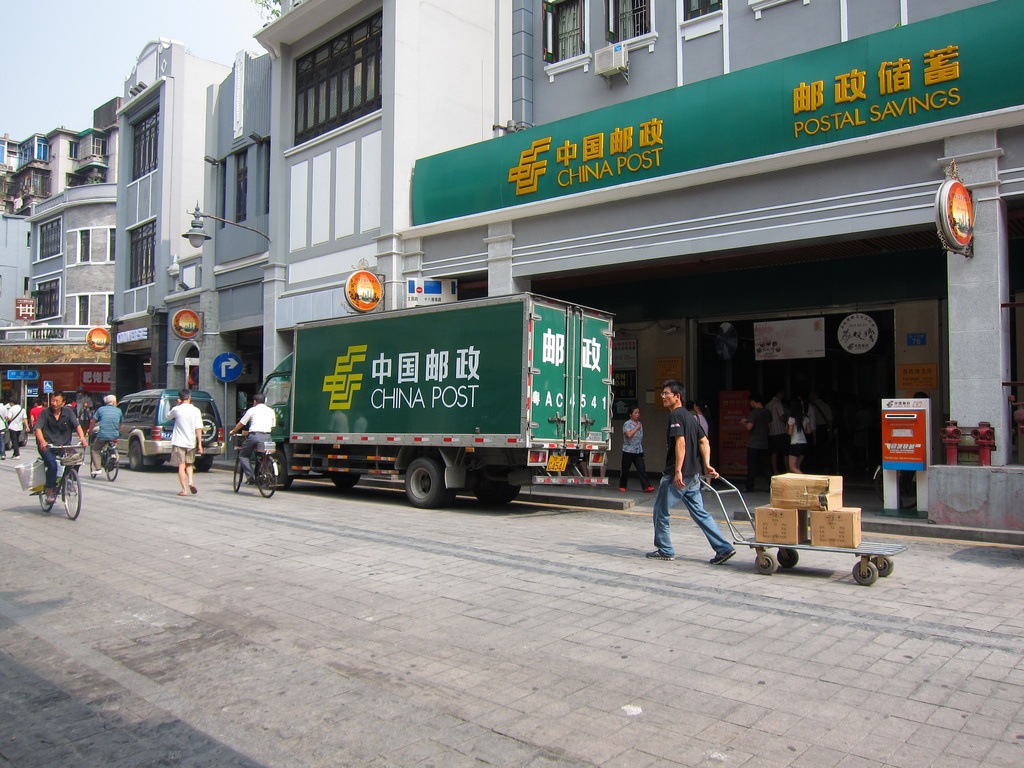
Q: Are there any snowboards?
A: No, there are no snowboards.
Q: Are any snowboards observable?
A: No, there are no snowboards.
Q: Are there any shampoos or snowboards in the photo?
A: No, there are no snowboards or shampoos.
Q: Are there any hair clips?
A: No, there are no hair clips.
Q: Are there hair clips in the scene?
A: No, there are no hair clips.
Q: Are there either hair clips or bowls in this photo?
A: No, there are no hair clips or bowls.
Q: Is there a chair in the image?
A: No, there are no chairs.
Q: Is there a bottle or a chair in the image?
A: No, there are no chairs or bottles.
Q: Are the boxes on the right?
A: Yes, the boxes are on the right of the image.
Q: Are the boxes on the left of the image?
A: No, the boxes are on the right of the image.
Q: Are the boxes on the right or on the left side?
A: The boxes are on the right of the image.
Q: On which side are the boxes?
A: The boxes are on the right of the image.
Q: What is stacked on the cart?
A: The boxes are stacked on the cart.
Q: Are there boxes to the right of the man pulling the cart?
A: Yes, there are boxes to the right of the man.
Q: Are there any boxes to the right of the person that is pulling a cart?
A: Yes, there are boxes to the right of the man.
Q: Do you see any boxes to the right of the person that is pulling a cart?
A: Yes, there are boxes to the right of the man.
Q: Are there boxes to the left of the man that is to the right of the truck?
A: No, the boxes are to the right of the man.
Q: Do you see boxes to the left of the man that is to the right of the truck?
A: No, the boxes are to the right of the man.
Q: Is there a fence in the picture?
A: No, there are no fences.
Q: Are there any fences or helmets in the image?
A: No, there are no fences or helmets.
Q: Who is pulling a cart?
A: The man is pulling a cart.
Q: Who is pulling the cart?
A: The man is pulling a cart.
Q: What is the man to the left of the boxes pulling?
A: The man is pulling a cart.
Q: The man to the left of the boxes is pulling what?
A: The man is pulling a cart.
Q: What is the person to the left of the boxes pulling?
A: The man is pulling a cart.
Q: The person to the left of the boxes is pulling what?
A: The man is pulling a cart.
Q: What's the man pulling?
A: The man is pulling a cart.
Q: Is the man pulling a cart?
A: Yes, the man is pulling a cart.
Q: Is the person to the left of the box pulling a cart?
A: Yes, the man is pulling a cart.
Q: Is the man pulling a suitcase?
A: No, the man is pulling a cart.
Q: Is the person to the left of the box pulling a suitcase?
A: No, the man is pulling a cart.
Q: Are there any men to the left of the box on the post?
A: Yes, there is a man to the left of the box.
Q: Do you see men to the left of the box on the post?
A: Yes, there is a man to the left of the box.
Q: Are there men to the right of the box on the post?
A: No, the man is to the left of the box.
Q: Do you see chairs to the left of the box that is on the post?
A: No, there is a man to the left of the box.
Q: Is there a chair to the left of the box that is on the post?
A: No, there is a man to the left of the box.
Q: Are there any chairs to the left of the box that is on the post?
A: No, there is a man to the left of the box.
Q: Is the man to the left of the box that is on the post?
A: Yes, the man is to the left of the box.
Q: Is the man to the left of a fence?
A: No, the man is to the left of the box.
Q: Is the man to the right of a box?
A: No, the man is to the left of a box.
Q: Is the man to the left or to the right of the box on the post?
A: The man is to the left of the box.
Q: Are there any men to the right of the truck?
A: Yes, there is a man to the right of the truck.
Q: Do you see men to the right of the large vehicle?
A: Yes, there is a man to the right of the truck.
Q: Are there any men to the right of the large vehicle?
A: Yes, there is a man to the right of the truck.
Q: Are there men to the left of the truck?
A: No, the man is to the right of the truck.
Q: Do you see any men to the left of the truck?
A: No, the man is to the right of the truck.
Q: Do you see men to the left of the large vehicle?
A: No, the man is to the right of the truck.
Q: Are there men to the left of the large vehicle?
A: No, the man is to the right of the truck.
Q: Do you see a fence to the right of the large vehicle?
A: No, there is a man to the right of the truck.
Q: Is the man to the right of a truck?
A: Yes, the man is to the right of a truck.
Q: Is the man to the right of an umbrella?
A: No, the man is to the right of a truck.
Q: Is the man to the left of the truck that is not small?
A: No, the man is to the right of the truck.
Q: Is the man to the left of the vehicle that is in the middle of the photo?
A: No, the man is to the right of the truck.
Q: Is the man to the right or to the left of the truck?
A: The man is to the right of the truck.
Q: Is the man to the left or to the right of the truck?
A: The man is to the right of the truck.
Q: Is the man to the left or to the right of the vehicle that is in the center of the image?
A: The man is to the right of the truck.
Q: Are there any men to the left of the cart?
A: Yes, there is a man to the left of the cart.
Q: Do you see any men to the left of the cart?
A: Yes, there is a man to the left of the cart.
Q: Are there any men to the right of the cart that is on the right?
A: No, the man is to the left of the cart.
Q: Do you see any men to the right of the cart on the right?
A: No, the man is to the left of the cart.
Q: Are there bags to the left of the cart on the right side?
A: No, there is a man to the left of the cart.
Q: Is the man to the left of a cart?
A: Yes, the man is to the left of a cart.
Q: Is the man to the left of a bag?
A: No, the man is to the left of a cart.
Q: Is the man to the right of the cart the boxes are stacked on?
A: No, the man is to the left of the cart.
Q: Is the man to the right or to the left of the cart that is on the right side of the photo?
A: The man is to the left of the cart.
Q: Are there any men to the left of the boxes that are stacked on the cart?
A: Yes, there is a man to the left of the boxes.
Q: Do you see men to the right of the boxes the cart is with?
A: No, the man is to the left of the boxes.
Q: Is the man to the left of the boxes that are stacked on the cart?
A: Yes, the man is to the left of the boxes.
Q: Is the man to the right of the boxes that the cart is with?
A: No, the man is to the left of the boxes.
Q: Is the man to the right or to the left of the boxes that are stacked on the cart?
A: The man is to the left of the boxes.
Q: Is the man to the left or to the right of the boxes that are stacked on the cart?
A: The man is to the left of the boxes.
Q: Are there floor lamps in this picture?
A: No, there are no floor lamps.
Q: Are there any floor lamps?
A: No, there are no floor lamps.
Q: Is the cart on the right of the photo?
A: Yes, the cart is on the right of the image.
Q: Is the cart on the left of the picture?
A: No, the cart is on the right of the image.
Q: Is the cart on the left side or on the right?
A: The cart is on the right of the image.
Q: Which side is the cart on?
A: The cart is on the right of the image.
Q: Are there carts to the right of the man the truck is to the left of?
A: Yes, there is a cart to the right of the man.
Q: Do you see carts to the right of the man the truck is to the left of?
A: Yes, there is a cart to the right of the man.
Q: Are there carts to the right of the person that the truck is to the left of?
A: Yes, there is a cart to the right of the man.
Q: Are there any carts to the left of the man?
A: No, the cart is to the right of the man.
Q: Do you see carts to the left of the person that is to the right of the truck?
A: No, the cart is to the right of the man.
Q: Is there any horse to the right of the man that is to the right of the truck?
A: No, there is a cart to the right of the man.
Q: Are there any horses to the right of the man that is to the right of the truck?
A: No, there is a cart to the right of the man.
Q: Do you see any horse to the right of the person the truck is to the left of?
A: No, there is a cart to the right of the man.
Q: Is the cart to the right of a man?
A: Yes, the cart is to the right of a man.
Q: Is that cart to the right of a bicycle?
A: No, the cart is to the right of a man.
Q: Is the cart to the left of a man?
A: No, the cart is to the right of a man.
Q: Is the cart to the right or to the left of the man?
A: The cart is to the right of the man.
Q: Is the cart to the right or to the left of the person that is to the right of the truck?
A: The cart is to the right of the man.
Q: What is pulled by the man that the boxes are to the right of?
A: The cart is pulled by the man.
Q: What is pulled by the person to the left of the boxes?
A: The cart is pulled by the man.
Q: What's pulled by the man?
A: The cart is pulled by the man.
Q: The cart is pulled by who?
A: The cart is pulled by the man.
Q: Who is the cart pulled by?
A: The cart is pulled by the man.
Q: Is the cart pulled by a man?
A: Yes, the cart is pulled by a man.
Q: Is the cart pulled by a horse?
A: No, the cart is pulled by a man.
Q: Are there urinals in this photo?
A: No, there are no urinals.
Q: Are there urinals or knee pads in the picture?
A: No, there are no urinals or knee pads.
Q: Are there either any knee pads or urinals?
A: No, there are no urinals or knee pads.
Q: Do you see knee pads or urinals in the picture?
A: No, there are no urinals or knee pads.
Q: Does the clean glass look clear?
A: Yes, the glass is clear.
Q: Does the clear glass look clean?
A: Yes, the glass is clean.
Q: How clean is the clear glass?
A: The glass is clean.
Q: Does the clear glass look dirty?
A: No, the glass is clean.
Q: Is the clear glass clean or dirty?
A: The glass is clean.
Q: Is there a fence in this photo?
A: No, there are no fences.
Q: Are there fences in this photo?
A: No, there are no fences.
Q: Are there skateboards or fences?
A: No, there are no fences or skateboards.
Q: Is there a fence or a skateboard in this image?
A: No, there are no fences or skateboards.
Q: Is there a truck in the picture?
A: Yes, there is a truck.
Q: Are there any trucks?
A: Yes, there is a truck.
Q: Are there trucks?
A: Yes, there is a truck.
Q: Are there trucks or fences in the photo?
A: Yes, there is a truck.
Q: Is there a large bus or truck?
A: Yes, there is a large truck.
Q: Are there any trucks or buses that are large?
A: Yes, the truck is large.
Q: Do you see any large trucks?
A: Yes, there is a large truck.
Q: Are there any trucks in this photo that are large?
A: Yes, there is a truck that is large.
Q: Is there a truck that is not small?
A: Yes, there is a large truck.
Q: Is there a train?
A: No, there are no trains.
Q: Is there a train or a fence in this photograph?
A: No, there are no trains or fences.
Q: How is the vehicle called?
A: The vehicle is a truck.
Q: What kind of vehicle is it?
A: The vehicle is a truck.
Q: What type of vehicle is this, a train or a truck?
A: This is a truck.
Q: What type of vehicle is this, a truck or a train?
A: This is a truck.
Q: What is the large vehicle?
A: The vehicle is a truck.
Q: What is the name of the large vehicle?
A: The vehicle is a truck.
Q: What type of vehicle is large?
A: The vehicle is a truck.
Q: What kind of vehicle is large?
A: The vehicle is a truck.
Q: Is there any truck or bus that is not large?
A: No, there is a truck but it is large.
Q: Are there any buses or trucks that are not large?
A: No, there is a truck but it is large.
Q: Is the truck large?
A: Yes, the truck is large.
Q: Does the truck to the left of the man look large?
A: Yes, the truck is large.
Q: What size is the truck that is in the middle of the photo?
A: The truck is large.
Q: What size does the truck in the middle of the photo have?
A: The truck has large size.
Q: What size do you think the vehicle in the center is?
A: The truck is large.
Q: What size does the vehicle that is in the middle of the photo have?
A: The truck has large size.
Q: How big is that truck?
A: The truck is large.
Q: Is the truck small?
A: No, the truck is large.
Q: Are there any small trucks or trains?
A: No, there is a truck but it is large.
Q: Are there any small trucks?
A: No, there is a truck but it is large.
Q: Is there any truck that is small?
A: No, there is a truck but it is large.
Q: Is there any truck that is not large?
A: No, there is a truck but it is large.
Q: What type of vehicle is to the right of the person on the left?
A: The vehicle is a truck.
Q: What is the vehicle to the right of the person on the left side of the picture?
A: The vehicle is a truck.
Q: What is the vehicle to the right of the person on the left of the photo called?
A: The vehicle is a truck.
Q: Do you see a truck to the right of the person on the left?
A: Yes, there is a truck to the right of the person.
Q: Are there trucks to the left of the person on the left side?
A: No, the truck is to the right of the person.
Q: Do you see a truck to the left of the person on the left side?
A: No, the truck is to the right of the person.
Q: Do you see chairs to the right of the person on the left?
A: No, there is a truck to the right of the person.